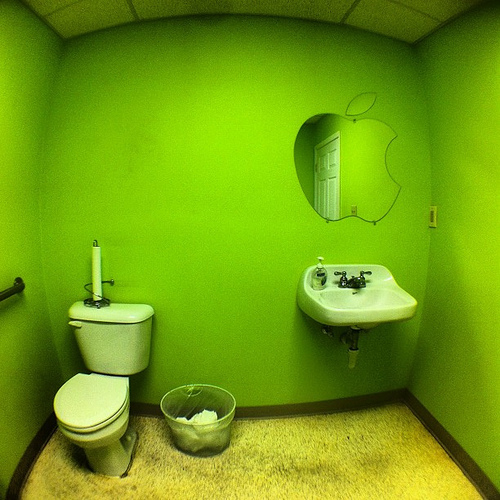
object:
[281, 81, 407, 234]
mirror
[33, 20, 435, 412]
wall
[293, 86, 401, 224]
apple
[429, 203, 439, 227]
outlet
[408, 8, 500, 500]
wall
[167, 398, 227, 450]
trash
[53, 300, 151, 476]
toilet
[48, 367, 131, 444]
seat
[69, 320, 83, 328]
handle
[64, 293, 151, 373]
tank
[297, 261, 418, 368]
basin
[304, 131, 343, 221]
reflection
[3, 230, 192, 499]
corner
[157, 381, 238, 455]
basket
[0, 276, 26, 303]
bar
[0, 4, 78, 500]
wall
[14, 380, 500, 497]
floor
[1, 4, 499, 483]
bathroom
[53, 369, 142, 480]
bowl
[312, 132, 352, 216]
bathroom door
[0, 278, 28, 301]
rod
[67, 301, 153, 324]
lid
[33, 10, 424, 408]
paint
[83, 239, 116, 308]
paper towel holder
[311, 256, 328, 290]
handwash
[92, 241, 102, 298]
candle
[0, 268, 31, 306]
pipeline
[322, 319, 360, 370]
pipeline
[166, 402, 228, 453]
papers